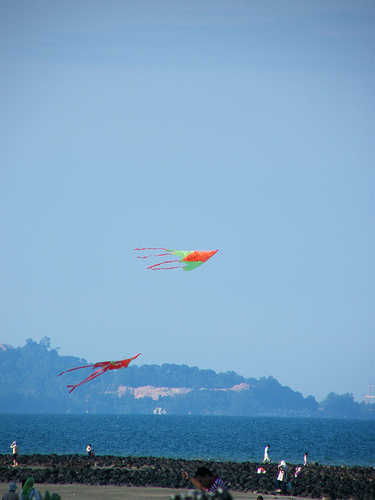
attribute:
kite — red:
[46, 343, 147, 407]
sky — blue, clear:
[31, 68, 321, 386]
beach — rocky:
[52, 455, 304, 496]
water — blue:
[9, 398, 369, 466]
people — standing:
[34, 425, 359, 473]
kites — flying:
[61, 211, 238, 373]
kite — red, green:
[54, 335, 197, 407]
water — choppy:
[33, 400, 354, 482]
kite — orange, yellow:
[109, 222, 201, 269]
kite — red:
[58, 345, 214, 424]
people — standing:
[164, 447, 337, 498]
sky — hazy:
[7, 337, 266, 420]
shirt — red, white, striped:
[209, 479, 227, 492]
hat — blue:
[6, 481, 17, 491]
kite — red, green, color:
[131, 244, 220, 271]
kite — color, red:
[52, 351, 142, 393]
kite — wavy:
[53, 351, 145, 390]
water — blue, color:
[128, 415, 239, 447]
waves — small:
[148, 421, 206, 450]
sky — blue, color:
[258, 125, 343, 316]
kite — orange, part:
[192, 250, 215, 261]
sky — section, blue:
[206, 282, 268, 335]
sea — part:
[200, 413, 230, 430]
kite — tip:
[214, 246, 219, 252]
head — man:
[191, 464, 217, 487]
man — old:
[7, 438, 20, 466]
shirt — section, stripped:
[204, 474, 229, 492]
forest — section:
[174, 368, 191, 380]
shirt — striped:
[187, 455, 241, 497]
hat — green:
[13, 480, 45, 497]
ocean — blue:
[171, 410, 331, 444]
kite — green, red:
[77, 202, 284, 311]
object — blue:
[286, 479, 313, 490]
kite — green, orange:
[126, 234, 266, 306]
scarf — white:
[270, 452, 291, 469]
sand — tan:
[67, 474, 160, 489]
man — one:
[256, 442, 274, 464]